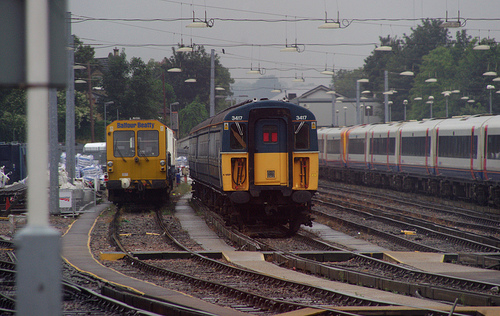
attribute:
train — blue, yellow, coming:
[189, 97, 324, 227]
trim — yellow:
[221, 152, 321, 190]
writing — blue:
[116, 122, 158, 128]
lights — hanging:
[186, 20, 212, 30]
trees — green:
[2, 17, 499, 144]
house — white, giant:
[292, 89, 385, 127]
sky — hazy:
[75, 2, 499, 103]